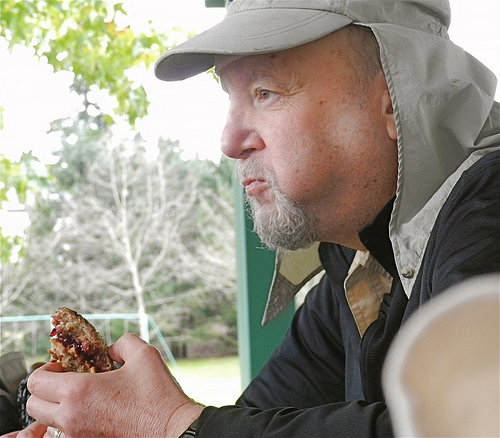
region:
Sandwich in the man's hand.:
[20, 282, 130, 403]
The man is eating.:
[177, 39, 377, 270]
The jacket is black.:
[283, 210, 478, 421]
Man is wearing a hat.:
[177, 2, 466, 50]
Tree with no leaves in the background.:
[77, 160, 235, 315]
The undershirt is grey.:
[386, 174, 480, 282]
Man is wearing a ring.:
[31, 418, 88, 436]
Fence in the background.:
[3, 312, 155, 372]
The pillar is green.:
[231, 223, 294, 373]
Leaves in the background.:
[3, 3, 153, 105]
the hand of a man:
[27, 328, 188, 437]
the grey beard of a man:
[238, 158, 311, 250]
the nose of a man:
[218, 96, 263, 156]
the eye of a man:
[255, 85, 280, 105]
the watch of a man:
[179, 399, 216, 436]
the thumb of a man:
[108, 327, 157, 367]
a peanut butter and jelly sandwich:
[50, 306, 110, 373]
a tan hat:
[153, 1, 450, 84]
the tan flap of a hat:
[357, 17, 496, 293]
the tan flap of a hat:
[260, 238, 335, 323]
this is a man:
[128, 33, 480, 338]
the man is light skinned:
[301, 119, 373, 212]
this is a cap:
[201, 14, 290, 51]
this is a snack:
[48, 315, 95, 362]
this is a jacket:
[252, 350, 342, 436]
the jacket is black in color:
[294, 344, 323, 376]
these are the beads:
[272, 207, 309, 247]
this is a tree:
[81, 50, 161, 252]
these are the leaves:
[51, 31, 133, 83]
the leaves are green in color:
[66, 32, 100, 70]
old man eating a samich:
[0, 5, 495, 426]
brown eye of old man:
[250, 80, 282, 106]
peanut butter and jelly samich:
[36, 310, 116, 375]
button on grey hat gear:
[395, 260, 410, 285]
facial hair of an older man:
[235, 150, 320, 250]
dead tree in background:
[50, 120, 180, 336]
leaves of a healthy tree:
[5, 0, 150, 135]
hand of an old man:
[26, 335, 173, 435]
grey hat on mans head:
[151, 0, 471, 72]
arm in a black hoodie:
[162, 397, 379, 434]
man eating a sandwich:
[15, 20, 470, 433]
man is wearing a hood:
[169, 2, 499, 272]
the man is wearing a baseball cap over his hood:
[135, 11, 495, 96]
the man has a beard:
[208, 160, 330, 278]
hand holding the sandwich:
[10, 289, 178, 436]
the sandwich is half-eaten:
[21, 300, 151, 417]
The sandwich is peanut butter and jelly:
[20, 309, 135, 421]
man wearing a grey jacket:
[162, 161, 490, 424]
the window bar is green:
[212, 153, 327, 413]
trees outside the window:
[1, 14, 254, 380]